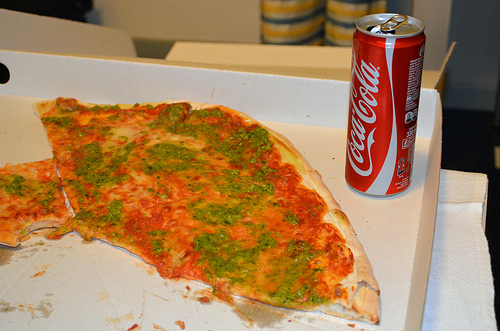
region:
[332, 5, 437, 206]
a tall can of soda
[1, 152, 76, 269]
a partially eaten slice of pizza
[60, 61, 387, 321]
partial pie in the cardboard box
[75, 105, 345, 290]
pizza topped with green herbs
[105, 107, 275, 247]
melted cheese on top of tomato sauce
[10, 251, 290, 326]
bits of food and oil stains in box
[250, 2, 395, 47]
hanging white, grey and yellow fabric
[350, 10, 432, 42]
pop top of open can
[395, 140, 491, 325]
white towel underneath pizza box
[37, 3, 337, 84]
top and side panels of pizza box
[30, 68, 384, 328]
a mostly eaten pizza.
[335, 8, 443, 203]
a can of coke on a pizza box.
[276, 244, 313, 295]
green toppings on a pizza.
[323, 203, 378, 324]
pizza crust.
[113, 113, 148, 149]
cheese on top of a pizza.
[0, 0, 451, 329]
an open pizza box.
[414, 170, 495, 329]
a section of a table.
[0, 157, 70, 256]
a half eaten slice of pizza.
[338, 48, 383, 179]
coca cola on the side of a can.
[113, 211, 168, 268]
sauce on a pizza.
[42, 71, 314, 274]
cheese pizza with pesto sauce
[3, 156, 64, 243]
half eaten pizza slice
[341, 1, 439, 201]
skinny can of Coke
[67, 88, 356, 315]
four slices of pizza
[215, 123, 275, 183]
green pesto sauce on pizza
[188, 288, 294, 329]
grease stains on box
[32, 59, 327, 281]
pizza in white box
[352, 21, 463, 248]
Coke can in white box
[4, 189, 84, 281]
pizza slice with bite taken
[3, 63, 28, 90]
hole in pizza box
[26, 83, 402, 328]
pizza on a table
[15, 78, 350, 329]
pizza with cheese and pesto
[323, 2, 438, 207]
coca cola can with logo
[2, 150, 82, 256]
slice of pizza with a bite out of it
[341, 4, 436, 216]
red and white can of soda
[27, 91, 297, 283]
green sauce on a pizza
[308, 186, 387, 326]
pizza crust broken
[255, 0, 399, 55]
blue and yellow stripes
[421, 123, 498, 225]
corner of pizza box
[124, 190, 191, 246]
melted cheese and pizza sauce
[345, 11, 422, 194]
a can of Coca-Cola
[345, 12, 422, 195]
the can is red with white lettering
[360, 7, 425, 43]
the can is opened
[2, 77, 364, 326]
a half-eaten pizza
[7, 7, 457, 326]
the pizza is in a box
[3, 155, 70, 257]
a slice of pizza with bites missing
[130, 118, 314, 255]
the pizza is covered in a weird green topping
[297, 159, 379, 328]
pizza crust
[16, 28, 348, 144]
the pizza box appears white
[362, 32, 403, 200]
a white swirl on the side of the can